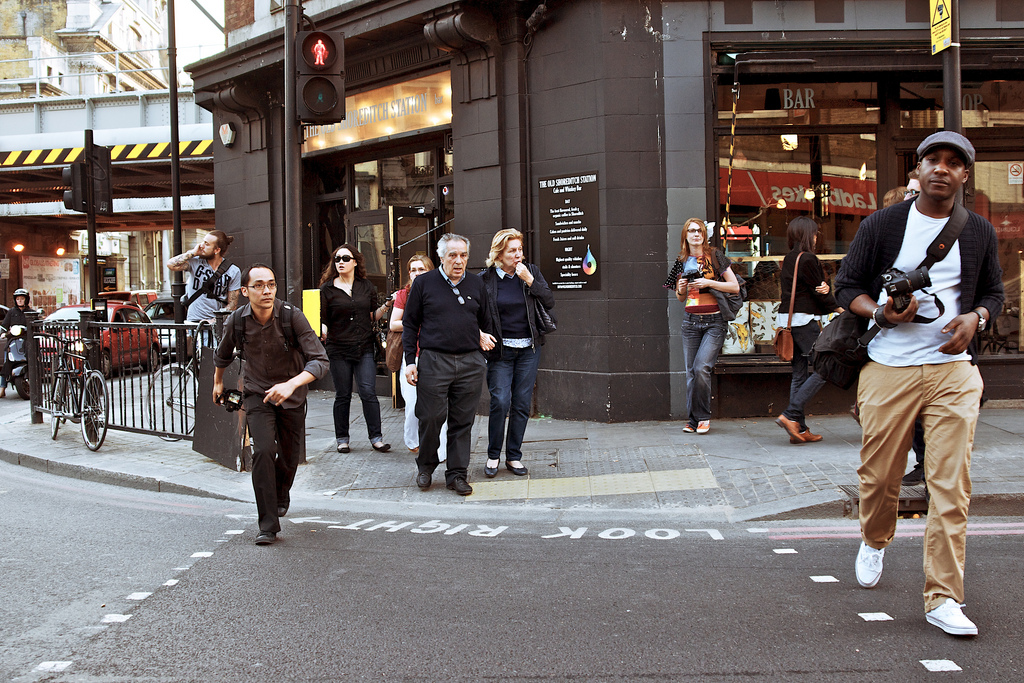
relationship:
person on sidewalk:
[393, 223, 517, 509] [240, 361, 910, 550]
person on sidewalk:
[781, 212, 832, 449] [280, 381, 1009, 509]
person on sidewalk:
[665, 219, 740, 429] [120, 376, 1021, 521]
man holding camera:
[833, 135, 1000, 644] [853, 245, 938, 328]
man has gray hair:
[397, 223, 491, 502] [434, 229, 474, 264]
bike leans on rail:
[58, 346, 119, 452] [23, 297, 279, 462]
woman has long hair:
[306, 229, 400, 465] [317, 242, 372, 290]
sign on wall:
[537, 162, 604, 297] [447, 16, 681, 431]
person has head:
[194, 257, 357, 571] [241, 257, 283, 320]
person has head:
[300, 225, 413, 457] [317, 245, 372, 285]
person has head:
[392, 223, 481, 505] [425, 229, 486, 286]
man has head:
[833, 135, 1000, 644] [887, 134, 976, 202]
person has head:
[388, 253, 460, 459] [397, 247, 434, 297]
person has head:
[164, 225, 234, 325] [194, 230, 234, 272]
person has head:
[373, 234, 451, 481] [397, 234, 436, 297]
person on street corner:
[194, 261, 338, 542] [40, 465, 875, 666]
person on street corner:
[392, 223, 481, 505] [30, 446, 877, 676]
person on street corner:
[464, 225, 557, 474] [108, 441, 958, 677]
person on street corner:
[665, 219, 740, 429] [53, 454, 916, 677]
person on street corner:
[794, 111, 983, 665] [108, 441, 958, 677]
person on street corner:
[388, 253, 460, 459] [108, 441, 958, 677]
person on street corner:
[305, 247, 392, 457] [53, 454, 916, 677]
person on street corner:
[162, 217, 245, 397] [23, 458, 966, 672]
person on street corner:
[8, 273, 58, 353] [6, 420, 1016, 663]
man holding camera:
[803, 95, 1000, 644] [876, 240, 954, 340]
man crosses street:
[803, 95, 1000, 644] [23, 480, 1017, 677]